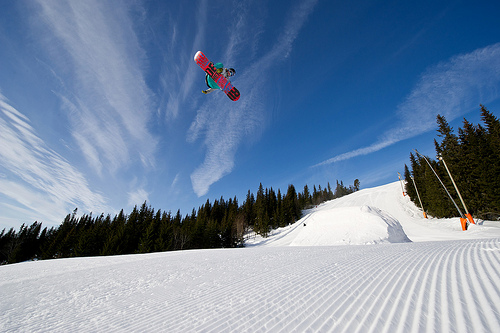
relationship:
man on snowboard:
[199, 61, 237, 92] [191, 49, 241, 106]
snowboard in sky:
[191, 49, 241, 106] [1, 4, 490, 228]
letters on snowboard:
[211, 68, 222, 84] [191, 49, 241, 106]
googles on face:
[229, 69, 236, 75] [227, 67, 238, 80]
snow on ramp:
[60, 260, 491, 328] [285, 205, 402, 249]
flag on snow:
[395, 168, 404, 182] [60, 260, 491, 328]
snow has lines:
[60, 260, 491, 328] [327, 267, 396, 298]